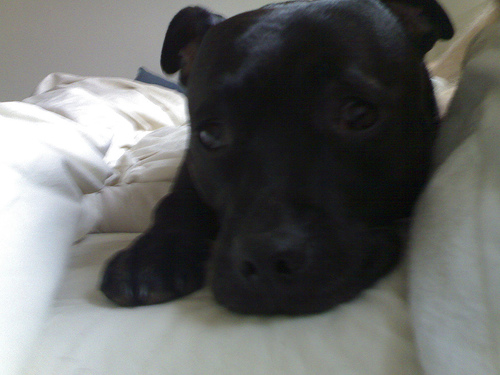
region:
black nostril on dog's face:
[232, 255, 260, 279]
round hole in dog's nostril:
[277, 244, 311, 281]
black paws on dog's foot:
[110, 271, 178, 302]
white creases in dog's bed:
[51, 147, 143, 214]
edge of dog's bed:
[69, 221, 115, 259]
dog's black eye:
[194, 117, 247, 146]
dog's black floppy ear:
[151, 10, 230, 63]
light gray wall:
[19, 10, 126, 57]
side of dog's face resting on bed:
[383, 70, 478, 205]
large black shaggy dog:
[72, 2, 459, 342]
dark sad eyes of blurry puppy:
[183, 92, 385, 157]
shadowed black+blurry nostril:
[237, 255, 257, 287]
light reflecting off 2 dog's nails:
[115, 272, 155, 310]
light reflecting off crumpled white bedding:
[1, 66, 191, 216]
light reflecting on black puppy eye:
[193, 113, 238, 158]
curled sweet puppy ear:
[153, 4, 231, 96]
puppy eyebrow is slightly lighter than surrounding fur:
[345, 60, 383, 100]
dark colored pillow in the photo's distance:
[129, 64, 194, 98]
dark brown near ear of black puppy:
[175, 34, 205, 91]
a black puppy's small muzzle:
[202, 233, 340, 323]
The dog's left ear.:
[156, 6, 216, 76]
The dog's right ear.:
[381, 1, 466, 53]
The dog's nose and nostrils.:
[239, 226, 305, 288]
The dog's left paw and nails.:
[101, 229, 211, 314]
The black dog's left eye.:
[193, 101, 240, 158]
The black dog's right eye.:
[328, 83, 387, 140]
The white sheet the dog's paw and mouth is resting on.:
[83, 233, 423, 373]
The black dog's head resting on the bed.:
[176, 3, 449, 313]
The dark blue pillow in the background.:
[137, 60, 179, 90]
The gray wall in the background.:
[1, 1, 204, 101]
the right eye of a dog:
[329, 86, 381, 137]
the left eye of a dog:
[184, 109, 239, 150]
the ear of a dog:
[161, 2, 223, 78]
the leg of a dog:
[101, 186, 209, 298]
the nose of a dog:
[233, 205, 308, 294]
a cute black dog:
[101, 1, 457, 305]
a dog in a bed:
[0, 0, 499, 374]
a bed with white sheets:
[1, 2, 498, 373]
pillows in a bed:
[0, 63, 180, 220]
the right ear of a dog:
[383, 0, 455, 43]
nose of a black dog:
[230, 228, 302, 274]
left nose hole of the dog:
[270, 248, 288, 279]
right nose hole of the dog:
[239, 255, 254, 280]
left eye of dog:
[342, 97, 373, 124]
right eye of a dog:
[194, 120, 235, 144]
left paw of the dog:
[85, 252, 185, 295]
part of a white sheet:
[130, 144, 159, 189]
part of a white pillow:
[441, 193, 481, 285]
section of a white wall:
[29, 15, 105, 52]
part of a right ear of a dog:
[150, 0, 184, 57]